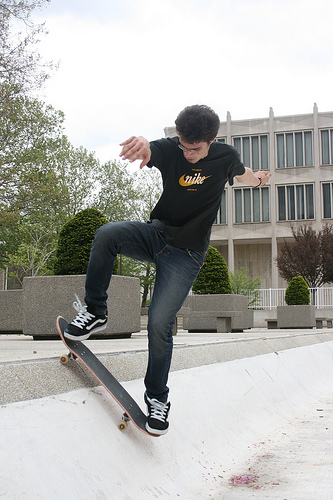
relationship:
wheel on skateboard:
[56, 349, 73, 368] [48, 302, 165, 452]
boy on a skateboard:
[20, 80, 269, 466] [47, 314, 175, 440]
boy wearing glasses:
[56, 105, 266, 438] [173, 139, 206, 164]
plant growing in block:
[284, 276, 312, 303] [278, 303, 315, 330]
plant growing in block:
[68, 216, 124, 283] [36, 265, 154, 318]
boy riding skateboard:
[56, 105, 266, 438] [55, 314, 160, 437]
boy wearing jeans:
[56, 105, 266, 438] [81, 217, 213, 405]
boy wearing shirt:
[56, 105, 266, 438] [155, 146, 226, 243]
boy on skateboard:
[56, 105, 266, 438] [53, 313, 157, 444]